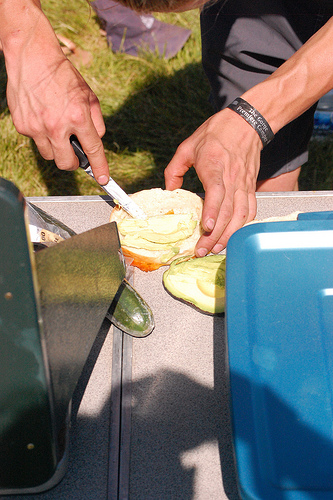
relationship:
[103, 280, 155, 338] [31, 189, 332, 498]
cucumber on table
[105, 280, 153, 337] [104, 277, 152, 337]
plastic warp cucumber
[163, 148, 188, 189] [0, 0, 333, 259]
thumb of a man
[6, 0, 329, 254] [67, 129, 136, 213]
man holds knife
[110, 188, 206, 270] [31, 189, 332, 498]
food on table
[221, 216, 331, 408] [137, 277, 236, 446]
lid on table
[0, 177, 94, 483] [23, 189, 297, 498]
lid on table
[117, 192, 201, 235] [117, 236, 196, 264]
slice of bread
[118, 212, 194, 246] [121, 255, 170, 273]
slice of bread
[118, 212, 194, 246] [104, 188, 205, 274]
slice of food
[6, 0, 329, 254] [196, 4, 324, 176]
man standing shorts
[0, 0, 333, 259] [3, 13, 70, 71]
man standing wrist